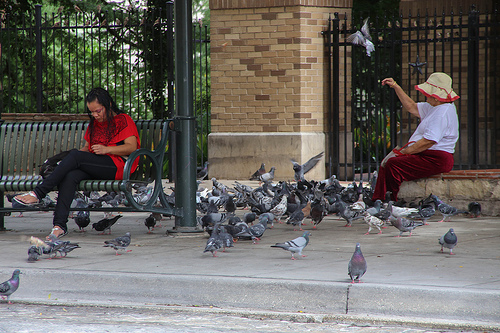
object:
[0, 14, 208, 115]
fence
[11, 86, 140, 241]
woman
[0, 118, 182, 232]
bench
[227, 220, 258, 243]
bird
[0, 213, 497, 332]
ground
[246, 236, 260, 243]
spot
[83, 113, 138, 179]
shirt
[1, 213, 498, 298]
sidewalk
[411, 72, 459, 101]
hat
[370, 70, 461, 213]
woman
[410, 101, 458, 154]
shirt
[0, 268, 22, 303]
bird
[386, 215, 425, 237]
bird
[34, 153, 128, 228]
pants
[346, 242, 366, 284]
bird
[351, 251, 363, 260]
spot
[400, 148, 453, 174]
bottoms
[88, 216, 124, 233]
bird